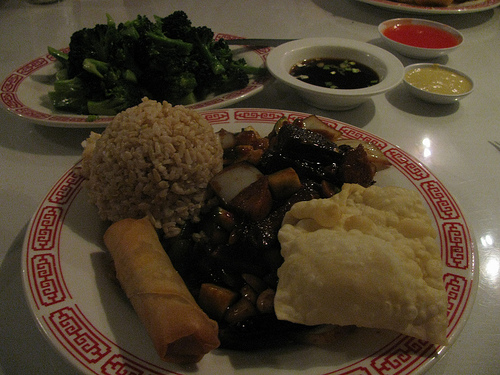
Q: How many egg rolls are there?
A: Two.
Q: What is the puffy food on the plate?
A: Wonton.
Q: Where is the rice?
A: Plate.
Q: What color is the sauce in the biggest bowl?
A: Brown.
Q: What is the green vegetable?
A: Broccoli.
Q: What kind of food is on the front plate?
A: Asian.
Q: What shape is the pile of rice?
A: Round.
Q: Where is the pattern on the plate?
A: Edges.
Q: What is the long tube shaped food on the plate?
A: Egg roll.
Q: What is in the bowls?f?
A: Sauces.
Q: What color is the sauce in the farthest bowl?
A: Orange.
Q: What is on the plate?
A: Dinner.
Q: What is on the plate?
A: Food.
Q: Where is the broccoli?
A: On plate.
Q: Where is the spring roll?
A: On the left.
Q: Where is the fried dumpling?
A: On right.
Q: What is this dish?
A: Meat and veggies.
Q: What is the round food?
A: Rice.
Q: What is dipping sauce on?
A: White dish.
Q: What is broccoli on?
A: Plate.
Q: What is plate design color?
A: Red.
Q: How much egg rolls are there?
A: One.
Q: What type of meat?
A: Rib.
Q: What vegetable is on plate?
A: Broccoli.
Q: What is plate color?
A: White and red.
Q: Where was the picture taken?
A: The restaurant.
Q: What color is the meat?
A: Black.